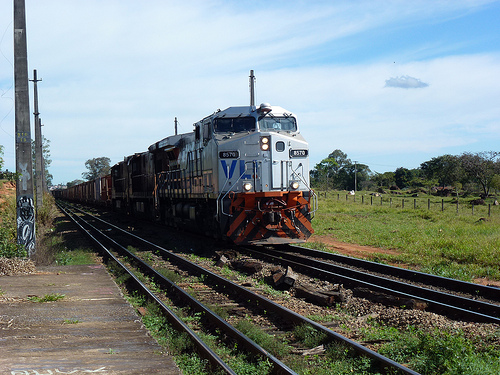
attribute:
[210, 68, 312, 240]
front end — orange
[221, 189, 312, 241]
stripes — black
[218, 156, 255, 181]
writing — blue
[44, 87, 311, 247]
train — long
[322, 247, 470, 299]
train tracks —  train's 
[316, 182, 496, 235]
fencing — wood, wire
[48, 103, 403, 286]
train —  coming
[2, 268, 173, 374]
platform — wooden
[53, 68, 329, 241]
train — for cargo, the Front , long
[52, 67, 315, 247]
freight train — for  freight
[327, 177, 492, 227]
fence — in background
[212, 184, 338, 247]
bumper — red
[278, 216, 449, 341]
dirt — brown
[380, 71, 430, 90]
cloud — small, gray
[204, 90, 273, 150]
sky — light, blue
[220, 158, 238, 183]
letter — blue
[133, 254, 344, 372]
lines —  3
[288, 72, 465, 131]
clouds — Wispy , white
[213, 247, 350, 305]
wood — in Pile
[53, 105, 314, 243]
train — a freight train, white,  the front, modern